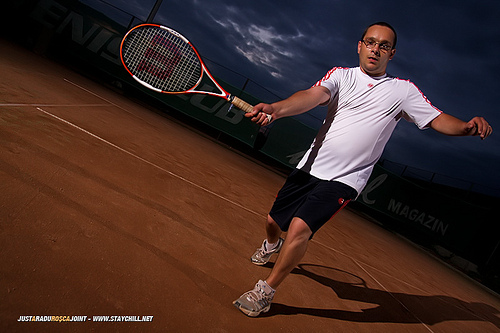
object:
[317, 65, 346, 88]
stripe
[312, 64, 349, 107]
sleeve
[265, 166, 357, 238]
shorts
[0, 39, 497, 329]
ground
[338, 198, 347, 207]
parts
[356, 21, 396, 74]
head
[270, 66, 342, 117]
arm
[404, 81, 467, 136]
arm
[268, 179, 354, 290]
leg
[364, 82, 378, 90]
sign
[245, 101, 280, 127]
hand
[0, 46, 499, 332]
tennis court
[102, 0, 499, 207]
sky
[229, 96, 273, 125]
handle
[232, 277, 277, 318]
shoe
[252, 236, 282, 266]
shoe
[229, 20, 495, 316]
man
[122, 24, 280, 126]
tennis racket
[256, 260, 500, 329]
shadow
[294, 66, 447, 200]
white shirt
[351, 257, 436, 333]
lines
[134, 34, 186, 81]
red w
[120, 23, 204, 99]
strings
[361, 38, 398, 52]
glasses